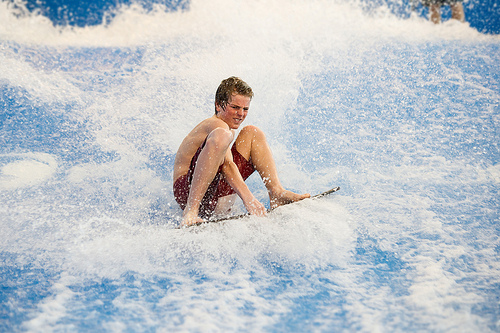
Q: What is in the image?
A: Surfboard.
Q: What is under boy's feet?
A: Skim board.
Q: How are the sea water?
A: White rough.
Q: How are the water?
A: Splashed into air.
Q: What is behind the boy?
A: Crest of wave.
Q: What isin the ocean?
A: Black board of a surfer.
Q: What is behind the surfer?
A: Foam spray from the water.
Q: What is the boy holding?
A: The surf board.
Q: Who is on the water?
A: The surfer is on the water.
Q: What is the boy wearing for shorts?
A: Red swim shorts.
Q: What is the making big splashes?
A: The surfer.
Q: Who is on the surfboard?
A: A boy.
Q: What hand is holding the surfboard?
A: The boy's right hand.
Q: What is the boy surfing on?
A: A large wave.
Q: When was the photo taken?
A: DAytime.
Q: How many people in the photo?
A: One.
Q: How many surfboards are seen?
A: One.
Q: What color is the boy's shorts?
A: Red.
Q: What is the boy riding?
A: Waves.